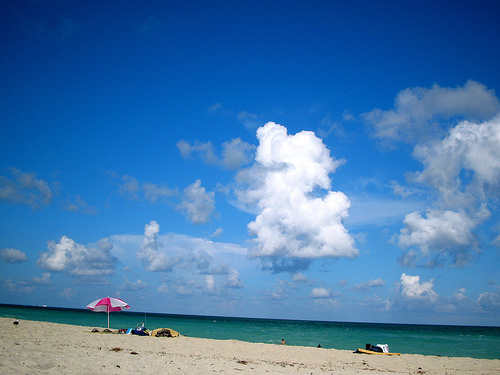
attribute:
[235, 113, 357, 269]
cloud — white, large, puffy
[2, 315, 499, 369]
sand — brown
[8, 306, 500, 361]
ocean — dark green, calm, green, blue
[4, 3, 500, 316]
sky — blue, bright blue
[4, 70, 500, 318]
clouds — puffy, white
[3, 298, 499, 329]
line — dark, thick, at horizon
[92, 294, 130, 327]
beach umbrella — pink, white, red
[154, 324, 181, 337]
blanket — yellow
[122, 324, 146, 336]
person — sun bathing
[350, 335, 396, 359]
belongings — on right side